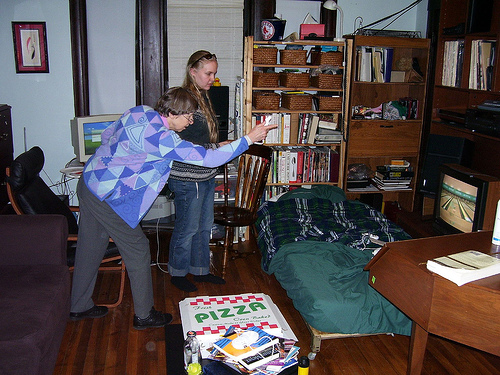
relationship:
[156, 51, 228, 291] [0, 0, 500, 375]
lady in bedroom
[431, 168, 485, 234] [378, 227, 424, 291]
computer on table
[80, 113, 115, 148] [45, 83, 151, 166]
computer in background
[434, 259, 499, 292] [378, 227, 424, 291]
book on table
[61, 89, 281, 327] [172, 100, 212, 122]
lady wears glasses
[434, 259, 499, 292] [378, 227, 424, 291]
book atop table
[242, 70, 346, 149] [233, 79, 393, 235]
books on shelve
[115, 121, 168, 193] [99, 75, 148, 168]
sweater on lady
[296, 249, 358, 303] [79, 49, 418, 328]
cover on bedroom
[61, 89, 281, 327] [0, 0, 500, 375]
lady in bedroom